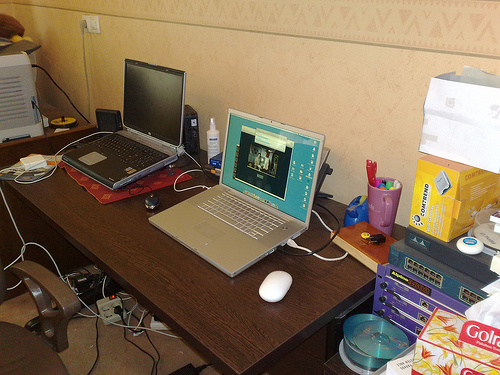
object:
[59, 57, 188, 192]
laptop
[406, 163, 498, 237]
box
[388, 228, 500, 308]
box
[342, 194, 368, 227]
tape dispenser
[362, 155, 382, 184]
scissors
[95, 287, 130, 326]
strip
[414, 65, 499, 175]
box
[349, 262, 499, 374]
boxes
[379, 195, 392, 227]
handle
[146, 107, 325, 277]
laptop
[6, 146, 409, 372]
table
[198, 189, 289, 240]
keyboard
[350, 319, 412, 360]
cds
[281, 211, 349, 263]
jack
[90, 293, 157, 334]
plugs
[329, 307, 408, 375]
stack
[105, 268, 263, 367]
desk top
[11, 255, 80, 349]
chair handle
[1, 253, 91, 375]
chair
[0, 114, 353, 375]
desk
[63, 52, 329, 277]
computers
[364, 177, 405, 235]
cup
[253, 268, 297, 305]
cordless mouse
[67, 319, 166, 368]
floor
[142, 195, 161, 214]
mouse